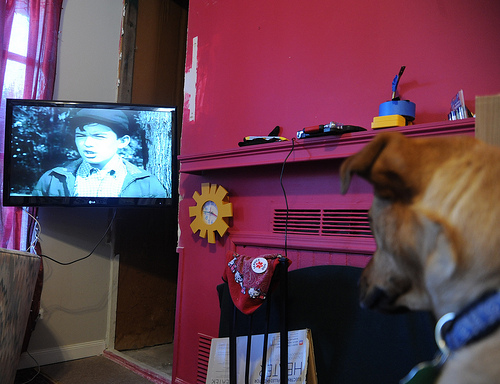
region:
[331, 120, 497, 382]
brown dog watching television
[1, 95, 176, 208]
black frame of flatscreen television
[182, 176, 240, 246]
yellow clock on the wall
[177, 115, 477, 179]
pink mantle above fireplace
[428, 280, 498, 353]
collar of the brown dog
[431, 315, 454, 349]
silver D ring on dog's collar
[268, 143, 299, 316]
black cord hanging from mantle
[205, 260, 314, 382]
white bag with black straps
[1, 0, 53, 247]
pink curtains over wi ndow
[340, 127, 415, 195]
ear of brown dog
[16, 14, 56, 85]
red curtains on the window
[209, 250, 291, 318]
red bandanda on a black bag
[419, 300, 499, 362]
collar on a dog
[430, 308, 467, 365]
metal ring on a collar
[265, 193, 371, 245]
red grates on a wall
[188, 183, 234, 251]
yellow clock on a wall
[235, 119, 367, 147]
items sitting on a ledge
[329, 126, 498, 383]
brown dog in a room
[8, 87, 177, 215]
television mounted in a doorway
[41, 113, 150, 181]
man on a tv screen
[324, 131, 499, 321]
brown dog head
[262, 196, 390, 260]
red grate on a wall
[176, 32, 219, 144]
white patch on a wall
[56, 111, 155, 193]
person on a telelvison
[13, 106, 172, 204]
black and white movie on television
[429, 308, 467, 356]
metal ring on a dog collar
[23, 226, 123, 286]
black wire hanging from the television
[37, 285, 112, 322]
shadow from a wire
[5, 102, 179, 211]
large television screen hanging up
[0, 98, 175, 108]
black bezel on television screen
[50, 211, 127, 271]
black cord hanging down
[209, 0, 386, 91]
red wall in room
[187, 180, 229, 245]
yellow flower clock on wall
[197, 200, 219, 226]
white clock in middle of frame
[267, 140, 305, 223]
black cord hanging down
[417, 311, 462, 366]
silver loop on dog collar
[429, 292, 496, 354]
black and blue dog collar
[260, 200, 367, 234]
red vent above fire place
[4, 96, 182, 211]
a large black t.v.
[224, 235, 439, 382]
part of a fireplace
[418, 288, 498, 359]
part of a dog's blue and black collar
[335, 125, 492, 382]
part of a brown dog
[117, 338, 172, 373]
part of a white floor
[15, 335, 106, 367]
part of a white floor trim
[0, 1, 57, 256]
part of a red curtain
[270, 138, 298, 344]
a long black cord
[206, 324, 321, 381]
part of a black and white bag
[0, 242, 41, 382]
part of a piece of furniture